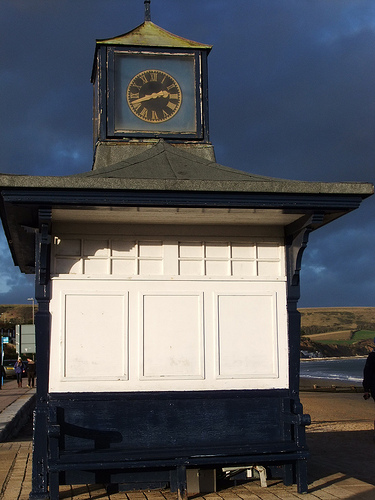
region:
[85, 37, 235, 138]
A clock on a structure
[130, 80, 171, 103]
The hands on a clock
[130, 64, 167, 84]
The numbers on a clock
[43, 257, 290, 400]
A white wall on a structure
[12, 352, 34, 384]
Two people walking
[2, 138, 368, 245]
The roof of a structure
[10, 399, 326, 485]
The base of a structure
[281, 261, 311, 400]
The edge of a structure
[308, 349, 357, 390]
Water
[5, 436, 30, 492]
Bricks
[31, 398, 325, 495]
one bench is seen.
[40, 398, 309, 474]
bench is black color.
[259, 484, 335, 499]
floor is brown color.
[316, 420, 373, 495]
shadow falls on ground.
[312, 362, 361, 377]
water is blue color.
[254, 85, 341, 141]
sky is blue color.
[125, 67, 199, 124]
one clock is seen.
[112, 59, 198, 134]
clock is black and brown color.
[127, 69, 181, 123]
time is 2.43 shown.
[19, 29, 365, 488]
day time picture.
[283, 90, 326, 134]
part of the sky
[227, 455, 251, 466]
base of a cupboard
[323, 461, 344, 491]
part of the floor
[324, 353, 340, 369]
part of a water body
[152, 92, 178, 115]
part of a roman clock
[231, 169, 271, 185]
part of a roof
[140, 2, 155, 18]
tip of a tower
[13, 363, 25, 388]
part of a black pant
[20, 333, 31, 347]
back of a sign board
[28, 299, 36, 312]
part of a post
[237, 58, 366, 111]
this is the sky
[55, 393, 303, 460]
the building skating is blue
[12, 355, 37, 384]
these are people walking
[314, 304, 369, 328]
the mountain is dry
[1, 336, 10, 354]
this is a sigh post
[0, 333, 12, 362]
the sigh post is blue in color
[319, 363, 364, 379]
this is water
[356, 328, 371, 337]
the grass is green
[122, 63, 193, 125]
this is a clock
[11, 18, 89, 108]
the sky is dull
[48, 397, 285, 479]
One bench is seen.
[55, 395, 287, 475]
Bench is black color.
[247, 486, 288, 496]
Floor is brown color.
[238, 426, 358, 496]
Shadow falls on ground.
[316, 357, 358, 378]
Water is blue color.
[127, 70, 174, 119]
2.43 time is seen.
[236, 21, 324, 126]
Sky is blue color.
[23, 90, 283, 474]
Day time picture.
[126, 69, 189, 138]
Clock is brown and black color.